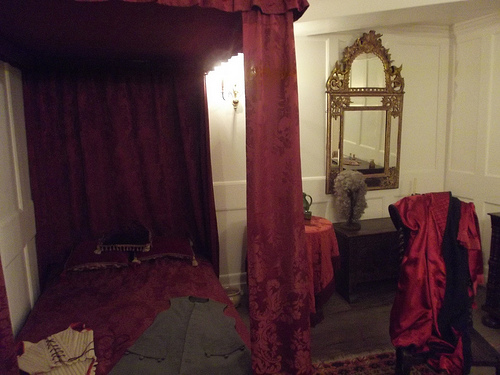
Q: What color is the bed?
A: Red.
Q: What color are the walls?
A: White.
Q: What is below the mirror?
A: A wig stand.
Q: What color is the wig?
A: Grey.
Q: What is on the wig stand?
A: A wig.